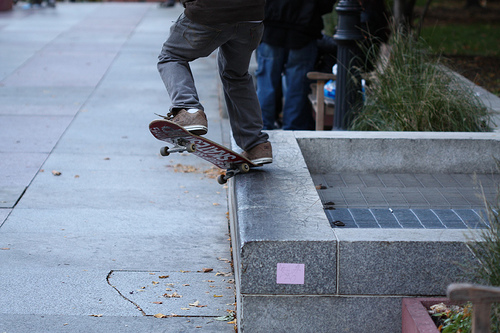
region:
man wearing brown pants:
[147, 11, 272, 136]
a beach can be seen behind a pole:
[301, 63, 368, 131]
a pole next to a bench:
[328, 1, 362, 135]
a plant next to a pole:
[351, 18, 496, 134]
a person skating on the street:
[134, 12, 276, 198]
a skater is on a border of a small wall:
[148, 1, 293, 185]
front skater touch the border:
[226, 144, 295, 197]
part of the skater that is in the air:
[144, 108, 234, 183]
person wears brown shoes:
[148, 89, 278, 174]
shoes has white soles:
[160, 99, 285, 176]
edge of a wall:
[246, 233, 256, 246]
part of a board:
[226, 155, 230, 160]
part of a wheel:
[185, 125, 193, 150]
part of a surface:
[163, 277, 180, 297]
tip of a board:
[163, 127, 172, 144]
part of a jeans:
[178, 72, 189, 92]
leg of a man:
[301, 101, 303, 106]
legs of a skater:
[136, 3, 280, 181]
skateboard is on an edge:
[140, 0, 275, 183]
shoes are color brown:
[153, 93, 294, 167]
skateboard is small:
[138, 115, 267, 190]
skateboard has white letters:
[134, 113, 257, 185]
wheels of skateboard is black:
[155, 138, 258, 191]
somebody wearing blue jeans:
[248, 0, 328, 130]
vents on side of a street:
[326, 186, 495, 228]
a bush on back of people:
[364, 50, 488, 130]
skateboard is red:
[149, 114, 270, 201]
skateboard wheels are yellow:
[185, 133, 204, 163]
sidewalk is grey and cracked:
[6, 1, 231, 326]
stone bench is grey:
[245, 148, 495, 322]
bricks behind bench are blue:
[325, 191, 495, 228]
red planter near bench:
[398, 299, 489, 331]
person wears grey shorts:
[159, 19, 270, 148]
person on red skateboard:
[156, 119, 261, 171]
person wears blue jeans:
[248, 0, 319, 119]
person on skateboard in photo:
[124, 70, 288, 187]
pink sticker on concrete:
[254, 244, 338, 294]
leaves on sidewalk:
[137, 132, 225, 330]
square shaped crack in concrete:
[55, 237, 190, 325]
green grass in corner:
[340, 38, 495, 155]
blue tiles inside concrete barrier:
[324, 157, 476, 238]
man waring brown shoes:
[137, 87, 295, 179]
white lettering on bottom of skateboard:
[142, 125, 262, 186]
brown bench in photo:
[295, 20, 412, 128]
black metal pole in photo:
[320, 4, 392, 149]